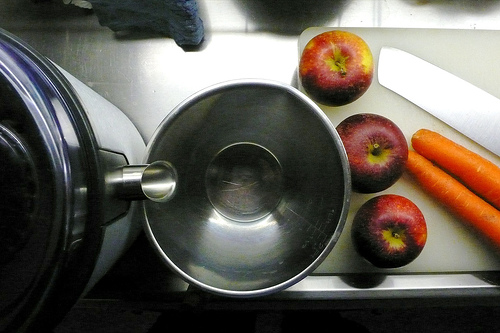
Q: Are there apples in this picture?
A: Yes, there is an apple.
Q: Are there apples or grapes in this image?
A: Yes, there is an apple.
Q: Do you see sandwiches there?
A: No, there are no sandwiches.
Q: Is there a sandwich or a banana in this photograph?
A: No, there are no sandwiches or bananas.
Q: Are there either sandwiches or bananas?
A: No, there are no sandwiches or bananas.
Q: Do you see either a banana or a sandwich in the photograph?
A: No, there are no sandwiches or bananas.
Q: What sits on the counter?
A: The apple sits on the counter.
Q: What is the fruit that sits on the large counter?
A: The fruit is an apple.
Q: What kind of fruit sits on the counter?
A: The fruit is an apple.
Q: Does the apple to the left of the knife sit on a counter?
A: Yes, the apple sits on a counter.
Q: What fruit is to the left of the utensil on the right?
A: The fruit is an apple.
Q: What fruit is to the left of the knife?
A: The fruit is an apple.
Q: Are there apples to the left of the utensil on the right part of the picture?
A: Yes, there is an apple to the left of the knife.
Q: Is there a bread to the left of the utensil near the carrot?
A: No, there is an apple to the left of the knife.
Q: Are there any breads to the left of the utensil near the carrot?
A: No, there is an apple to the left of the knife.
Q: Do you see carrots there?
A: Yes, there is a carrot.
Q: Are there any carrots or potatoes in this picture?
A: Yes, there is a carrot.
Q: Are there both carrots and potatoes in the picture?
A: No, there is a carrot but no potatoes.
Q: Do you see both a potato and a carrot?
A: No, there is a carrot but no potatoes.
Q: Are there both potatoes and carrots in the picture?
A: No, there is a carrot but no potatoes.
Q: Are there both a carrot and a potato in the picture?
A: No, there is a carrot but no potatoes.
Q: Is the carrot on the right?
A: Yes, the carrot is on the right of the image.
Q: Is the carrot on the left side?
A: No, the carrot is on the right of the image.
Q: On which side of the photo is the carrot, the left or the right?
A: The carrot is on the right of the image.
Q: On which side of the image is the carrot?
A: The carrot is on the right of the image.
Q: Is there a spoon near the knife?
A: No, there is a carrot near the knife.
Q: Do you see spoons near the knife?
A: No, there is a carrot near the knife.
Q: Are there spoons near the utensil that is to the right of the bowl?
A: No, there is a carrot near the knife.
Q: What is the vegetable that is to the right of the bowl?
A: The vegetable is a carrot.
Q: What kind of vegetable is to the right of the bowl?
A: The vegetable is a carrot.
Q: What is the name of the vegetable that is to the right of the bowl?
A: The vegetable is a carrot.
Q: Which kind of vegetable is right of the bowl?
A: The vegetable is a carrot.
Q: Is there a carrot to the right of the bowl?
A: Yes, there is a carrot to the right of the bowl.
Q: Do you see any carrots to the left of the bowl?
A: No, the carrot is to the right of the bowl.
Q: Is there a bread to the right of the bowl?
A: No, there is a carrot to the right of the bowl.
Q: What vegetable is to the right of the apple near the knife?
A: The vegetable is a carrot.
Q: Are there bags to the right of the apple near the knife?
A: No, there is a carrot to the right of the apple.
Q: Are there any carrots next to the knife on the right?
A: Yes, there is a carrot next to the knife.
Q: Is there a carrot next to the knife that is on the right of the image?
A: Yes, there is a carrot next to the knife.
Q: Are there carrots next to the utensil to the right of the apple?
A: Yes, there is a carrot next to the knife.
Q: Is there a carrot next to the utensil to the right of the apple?
A: Yes, there is a carrot next to the knife.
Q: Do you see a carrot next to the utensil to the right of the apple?
A: Yes, there is a carrot next to the knife.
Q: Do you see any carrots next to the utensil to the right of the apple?
A: Yes, there is a carrot next to the knife.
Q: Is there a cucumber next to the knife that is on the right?
A: No, there is a carrot next to the knife.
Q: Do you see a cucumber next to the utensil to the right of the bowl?
A: No, there is a carrot next to the knife.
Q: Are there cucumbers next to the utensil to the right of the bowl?
A: No, there is a carrot next to the knife.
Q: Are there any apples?
A: Yes, there is an apple.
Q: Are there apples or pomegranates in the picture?
A: Yes, there is an apple.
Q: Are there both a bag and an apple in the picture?
A: No, there is an apple but no bags.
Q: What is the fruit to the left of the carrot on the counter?
A: The fruit is an apple.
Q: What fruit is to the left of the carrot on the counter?
A: The fruit is an apple.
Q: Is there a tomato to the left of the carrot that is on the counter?
A: No, there is an apple to the left of the carrot.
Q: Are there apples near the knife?
A: Yes, there is an apple near the knife.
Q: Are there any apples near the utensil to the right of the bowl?
A: Yes, there is an apple near the knife.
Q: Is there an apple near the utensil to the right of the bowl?
A: Yes, there is an apple near the knife.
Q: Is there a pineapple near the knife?
A: No, there is an apple near the knife.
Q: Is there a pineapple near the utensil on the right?
A: No, there is an apple near the knife.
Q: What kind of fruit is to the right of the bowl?
A: The fruit is an apple.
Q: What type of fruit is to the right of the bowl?
A: The fruit is an apple.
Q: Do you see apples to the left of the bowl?
A: No, the apple is to the right of the bowl.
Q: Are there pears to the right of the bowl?
A: No, there is an apple to the right of the bowl.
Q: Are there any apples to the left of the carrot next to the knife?
A: Yes, there is an apple to the left of the carrot.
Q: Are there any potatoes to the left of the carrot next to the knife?
A: No, there is an apple to the left of the carrot.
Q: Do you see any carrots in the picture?
A: Yes, there is a carrot.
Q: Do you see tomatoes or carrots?
A: Yes, there is a carrot.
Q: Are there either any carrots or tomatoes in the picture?
A: Yes, there is a carrot.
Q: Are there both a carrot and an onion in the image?
A: No, there is a carrot but no onions.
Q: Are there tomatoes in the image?
A: No, there are no tomatoes.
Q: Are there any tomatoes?
A: No, there are no tomatoes.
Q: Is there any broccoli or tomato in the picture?
A: No, there are no tomatoes or broccoli.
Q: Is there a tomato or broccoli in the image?
A: No, there are no tomatoes or broccoli.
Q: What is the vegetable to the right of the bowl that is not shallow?
A: The vegetable is a carrot.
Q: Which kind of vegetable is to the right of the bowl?
A: The vegetable is a carrot.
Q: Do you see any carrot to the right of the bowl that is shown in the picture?
A: Yes, there is a carrot to the right of the bowl.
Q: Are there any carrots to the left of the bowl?
A: No, the carrot is to the right of the bowl.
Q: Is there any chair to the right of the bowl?
A: No, there is a carrot to the right of the bowl.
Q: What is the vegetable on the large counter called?
A: The vegetable is a carrot.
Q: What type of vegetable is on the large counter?
A: The vegetable is a carrot.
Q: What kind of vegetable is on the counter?
A: The vegetable is a carrot.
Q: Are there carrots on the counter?
A: Yes, there is a carrot on the counter.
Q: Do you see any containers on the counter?
A: No, there is a carrot on the counter.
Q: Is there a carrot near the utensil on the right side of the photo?
A: Yes, there is a carrot near the knife.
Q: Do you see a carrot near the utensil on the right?
A: Yes, there is a carrot near the knife.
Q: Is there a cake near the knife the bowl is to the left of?
A: No, there is a carrot near the knife.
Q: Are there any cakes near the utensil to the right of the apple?
A: No, there is a carrot near the knife.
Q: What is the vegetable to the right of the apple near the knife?
A: The vegetable is a carrot.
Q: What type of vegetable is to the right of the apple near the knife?
A: The vegetable is a carrot.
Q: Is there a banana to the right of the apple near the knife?
A: No, there is a carrot to the right of the apple.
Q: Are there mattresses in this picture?
A: No, there are no mattresses.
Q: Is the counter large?
A: Yes, the counter is large.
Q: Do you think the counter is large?
A: Yes, the counter is large.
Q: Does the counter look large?
A: Yes, the counter is large.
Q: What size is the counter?
A: The counter is large.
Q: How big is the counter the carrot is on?
A: The counter is large.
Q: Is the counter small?
A: No, the counter is large.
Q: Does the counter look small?
A: No, the counter is large.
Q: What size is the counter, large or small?
A: The counter is large.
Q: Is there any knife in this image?
A: Yes, there is a knife.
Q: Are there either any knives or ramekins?
A: Yes, there is a knife.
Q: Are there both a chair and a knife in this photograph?
A: No, there is a knife but no chairs.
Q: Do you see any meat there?
A: No, there is no meat.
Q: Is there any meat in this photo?
A: No, there is no meat.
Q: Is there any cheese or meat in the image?
A: No, there are no meat or cheese.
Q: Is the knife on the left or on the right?
A: The knife is on the right of the image.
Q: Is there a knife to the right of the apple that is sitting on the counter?
A: Yes, there is a knife to the right of the apple.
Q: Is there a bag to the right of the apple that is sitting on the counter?
A: No, there is a knife to the right of the apple.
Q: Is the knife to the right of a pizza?
A: No, the knife is to the right of the apple.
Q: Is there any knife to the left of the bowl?
A: No, the knife is to the right of the bowl.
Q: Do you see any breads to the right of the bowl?
A: No, there is a knife to the right of the bowl.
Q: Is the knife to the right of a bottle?
A: No, the knife is to the right of the bowl.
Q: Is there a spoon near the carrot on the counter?
A: No, there is a knife near the carrot.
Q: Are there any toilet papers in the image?
A: No, there are no toilet papers.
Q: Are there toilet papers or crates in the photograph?
A: No, there are no toilet papers or crates.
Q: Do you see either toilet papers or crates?
A: No, there are no toilet papers or crates.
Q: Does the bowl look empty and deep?
A: Yes, the bowl is empty and deep.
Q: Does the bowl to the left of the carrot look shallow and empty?
A: No, the bowl is empty but deep.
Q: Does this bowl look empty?
A: Yes, the bowl is empty.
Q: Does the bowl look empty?
A: Yes, the bowl is empty.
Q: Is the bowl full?
A: No, the bowl is empty.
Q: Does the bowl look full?
A: No, the bowl is empty.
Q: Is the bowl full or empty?
A: The bowl is empty.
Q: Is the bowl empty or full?
A: The bowl is empty.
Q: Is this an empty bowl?
A: Yes, this is an empty bowl.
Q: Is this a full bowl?
A: No, this is an empty bowl.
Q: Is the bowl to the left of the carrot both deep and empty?
A: Yes, the bowl is deep and empty.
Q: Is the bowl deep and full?
A: No, the bowl is deep but empty.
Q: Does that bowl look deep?
A: Yes, the bowl is deep.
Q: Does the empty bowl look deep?
A: Yes, the bowl is deep.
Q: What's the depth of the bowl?
A: The bowl is deep.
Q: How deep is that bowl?
A: The bowl is deep.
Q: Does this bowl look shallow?
A: No, the bowl is deep.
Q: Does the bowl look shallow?
A: No, the bowl is deep.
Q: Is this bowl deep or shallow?
A: The bowl is deep.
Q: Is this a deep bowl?
A: Yes, this is a deep bowl.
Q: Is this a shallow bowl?
A: No, this is a deep bowl.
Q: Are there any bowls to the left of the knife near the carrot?
A: Yes, there is a bowl to the left of the knife.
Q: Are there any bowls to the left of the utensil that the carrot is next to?
A: Yes, there is a bowl to the left of the knife.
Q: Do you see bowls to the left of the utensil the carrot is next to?
A: Yes, there is a bowl to the left of the knife.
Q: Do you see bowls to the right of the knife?
A: No, the bowl is to the left of the knife.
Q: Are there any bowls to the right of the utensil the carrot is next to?
A: No, the bowl is to the left of the knife.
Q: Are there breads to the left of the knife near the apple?
A: No, there is a bowl to the left of the knife.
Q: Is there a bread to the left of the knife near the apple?
A: No, there is a bowl to the left of the knife.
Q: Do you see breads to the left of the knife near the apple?
A: No, there is a bowl to the left of the knife.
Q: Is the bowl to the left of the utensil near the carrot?
A: Yes, the bowl is to the left of the knife.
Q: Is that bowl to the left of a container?
A: No, the bowl is to the left of the knife.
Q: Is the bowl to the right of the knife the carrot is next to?
A: No, the bowl is to the left of the knife.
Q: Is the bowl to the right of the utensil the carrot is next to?
A: No, the bowl is to the left of the knife.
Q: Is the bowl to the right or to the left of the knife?
A: The bowl is to the left of the knife.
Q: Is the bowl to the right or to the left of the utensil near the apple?
A: The bowl is to the left of the knife.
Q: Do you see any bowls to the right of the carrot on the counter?
A: No, the bowl is to the left of the carrot.